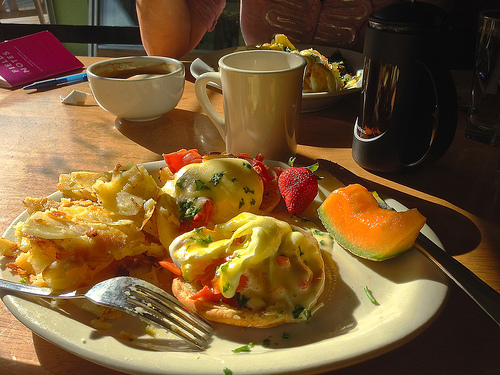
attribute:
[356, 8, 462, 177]
cup — hot, black, tall, silver, white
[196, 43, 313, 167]
cup — white, large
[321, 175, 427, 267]
cantaloupe — sitting, slice, orange, juicy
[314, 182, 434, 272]
slice — cantaloupe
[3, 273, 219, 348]
fork — dirty, resting, silver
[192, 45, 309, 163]
mug — white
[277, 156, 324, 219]
strawberry — red, plump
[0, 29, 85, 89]
book — purple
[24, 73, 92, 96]
pen — blue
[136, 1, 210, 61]
elbow — resting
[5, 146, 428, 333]
food — delicious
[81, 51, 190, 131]
cup — filled, white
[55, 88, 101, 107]
paper — small, folded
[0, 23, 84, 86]
notebook — pink, small